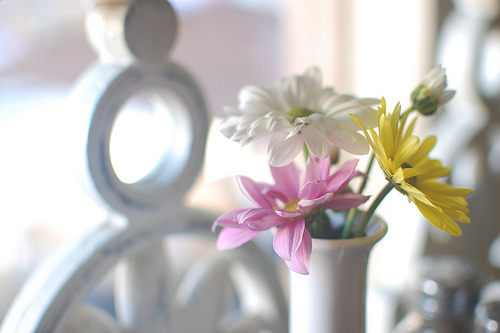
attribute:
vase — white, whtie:
[270, 207, 390, 332]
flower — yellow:
[352, 98, 472, 239]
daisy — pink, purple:
[208, 153, 372, 275]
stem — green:
[356, 180, 396, 238]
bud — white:
[218, 67, 384, 168]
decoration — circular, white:
[2, 1, 291, 332]